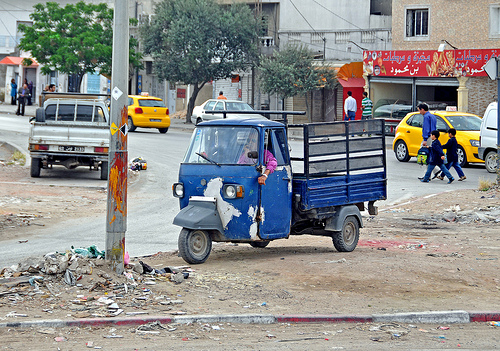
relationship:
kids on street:
[409, 122, 476, 179] [116, 105, 187, 255]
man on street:
[415, 103, 444, 181] [102, 115, 269, 254]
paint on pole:
[107, 103, 131, 230] [105, 140, 140, 266]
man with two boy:
[415, 103, 444, 181] [437, 118, 470, 178]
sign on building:
[360, 51, 498, 78] [356, 2, 498, 129]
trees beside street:
[257, 44, 336, 121] [1, 111, 498, 280]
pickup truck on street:
[20, 85, 135, 187] [39, 208, 152, 262]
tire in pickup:
[33, 106, 48, 127] [198, 190, 214, 261]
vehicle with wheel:
[173, 107, 390, 264] [330, 211, 361, 254]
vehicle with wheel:
[173, 107, 390, 264] [176, 225, 211, 264]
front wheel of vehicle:
[176, 221, 212, 266] [173, 107, 390, 264]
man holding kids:
[413, 102, 440, 176] [419, 127, 470, 185]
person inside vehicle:
[233, 130, 279, 186] [154, 119, 421, 267]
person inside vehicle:
[239, 132, 281, 186] [173, 107, 390, 264]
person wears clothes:
[233, 130, 279, 186] [238, 142, 278, 172]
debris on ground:
[0, 242, 195, 349] [2, 184, 496, 347]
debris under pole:
[0, 242, 203, 349] [96, 80, 132, 256]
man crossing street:
[415, 103, 444, 181] [17, 56, 264, 285]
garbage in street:
[128, 161, 164, 177] [8, 93, 440, 280]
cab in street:
[127, 92, 173, 134] [16, 103, 446, 287]